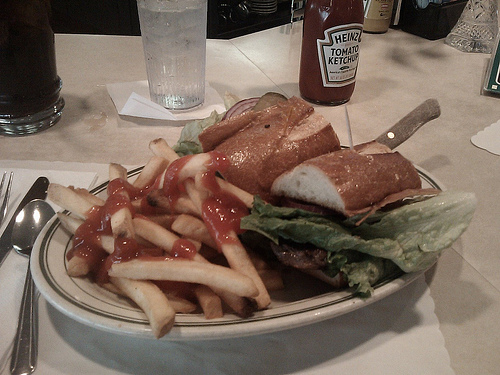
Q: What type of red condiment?
A: Ketchup.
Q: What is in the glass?
A: Water.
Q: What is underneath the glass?
A: Napkin.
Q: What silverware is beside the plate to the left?
A: Spoon.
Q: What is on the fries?
A: Ketchup.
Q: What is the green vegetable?
A: Lettuce.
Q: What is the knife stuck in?
A: Chicken.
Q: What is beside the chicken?
A: Bread.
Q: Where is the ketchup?
A: Fries.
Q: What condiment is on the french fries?
A: Ketchup.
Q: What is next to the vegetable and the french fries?
A: A sandwich.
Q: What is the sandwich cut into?
A: Halves.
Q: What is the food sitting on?
A: A plate.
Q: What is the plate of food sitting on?
A: A table.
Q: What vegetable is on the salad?
A: Lettuce.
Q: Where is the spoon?
A: To the left of the plate.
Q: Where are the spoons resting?
A: On the table.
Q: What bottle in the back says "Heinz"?
A: Ketchup.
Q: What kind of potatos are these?
A: French fried.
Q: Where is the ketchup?
A: On the fries.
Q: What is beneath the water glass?
A: A napkin.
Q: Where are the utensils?
A: To the left of the plate of food.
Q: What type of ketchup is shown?
A: Heinz Ketchup,.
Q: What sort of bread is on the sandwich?
A: French bread.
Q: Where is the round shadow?
A: Beneath the plate of food.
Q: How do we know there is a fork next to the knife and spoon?
A: A tine is visible.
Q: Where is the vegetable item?
A: Under a slice of French bread, reaching out over the edge of the plate,.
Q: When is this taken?
A: Dinner time.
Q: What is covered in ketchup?
A: Fries.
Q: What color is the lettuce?
A: Green.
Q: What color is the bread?
A: Brown.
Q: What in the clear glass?
A: Water.